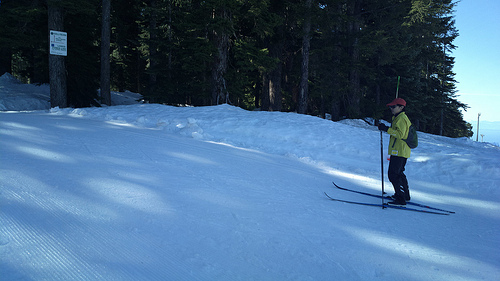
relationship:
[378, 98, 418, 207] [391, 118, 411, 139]
man with yellow jacket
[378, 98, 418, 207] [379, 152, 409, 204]
man with pants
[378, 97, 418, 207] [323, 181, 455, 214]
man on black skis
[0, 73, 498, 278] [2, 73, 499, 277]
snow covering ground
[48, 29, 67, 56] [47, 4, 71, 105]
sign on tree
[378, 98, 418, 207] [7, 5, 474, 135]
man at trees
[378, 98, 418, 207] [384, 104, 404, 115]
man wearing sunglasses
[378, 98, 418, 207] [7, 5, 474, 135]
man in trees